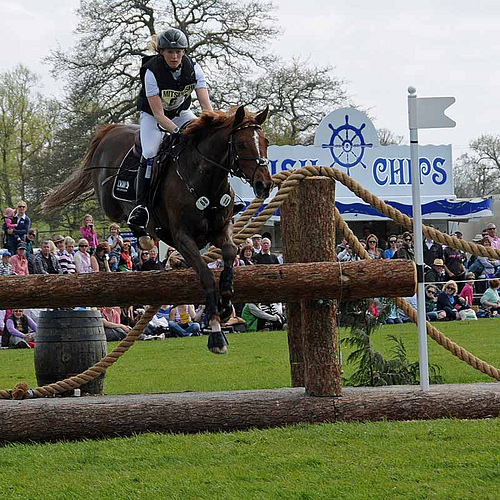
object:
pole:
[291, 170, 347, 400]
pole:
[279, 173, 321, 389]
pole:
[0, 257, 425, 309]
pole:
[0, 381, 500, 446]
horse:
[33, 100, 273, 355]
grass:
[0, 315, 499, 499]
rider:
[125, 24, 219, 242]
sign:
[262, 107, 456, 205]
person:
[0, 199, 30, 252]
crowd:
[0, 198, 500, 349]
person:
[79, 213, 98, 250]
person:
[105, 224, 125, 252]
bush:
[339, 289, 448, 393]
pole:
[403, 83, 472, 394]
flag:
[405, 94, 460, 131]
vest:
[134, 51, 200, 119]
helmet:
[153, 27, 190, 51]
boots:
[127, 154, 158, 229]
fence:
[1, 167, 500, 442]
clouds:
[0, 1, 498, 166]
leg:
[170, 228, 231, 355]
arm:
[193, 59, 214, 115]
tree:
[30, 0, 285, 234]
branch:
[189, 18, 278, 65]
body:
[92, 121, 221, 239]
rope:
[0, 161, 499, 402]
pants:
[138, 109, 203, 159]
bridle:
[182, 123, 273, 188]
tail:
[32, 119, 122, 217]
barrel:
[32, 301, 109, 398]